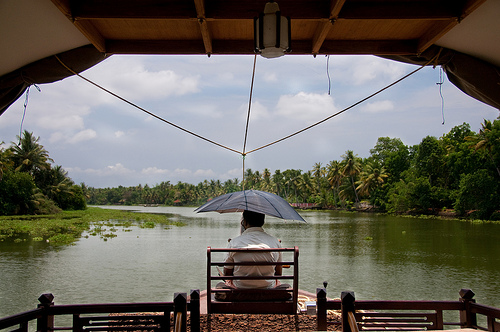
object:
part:
[216, 247, 289, 252]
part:
[245, 286, 279, 299]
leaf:
[406, 184, 412, 189]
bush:
[383, 175, 432, 217]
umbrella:
[190, 187, 308, 224]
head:
[239, 209, 267, 227]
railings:
[0, 290, 200, 331]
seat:
[208, 293, 298, 315]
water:
[0, 204, 499, 331]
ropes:
[244, 56, 437, 156]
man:
[222, 208, 284, 290]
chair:
[204, 245, 301, 331]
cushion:
[214, 280, 292, 302]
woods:
[375, 175, 387, 182]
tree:
[449, 172, 477, 216]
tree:
[336, 166, 360, 201]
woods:
[344, 175, 359, 201]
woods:
[283, 180, 292, 195]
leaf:
[22, 169, 31, 174]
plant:
[0, 172, 44, 211]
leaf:
[14, 166, 24, 170]